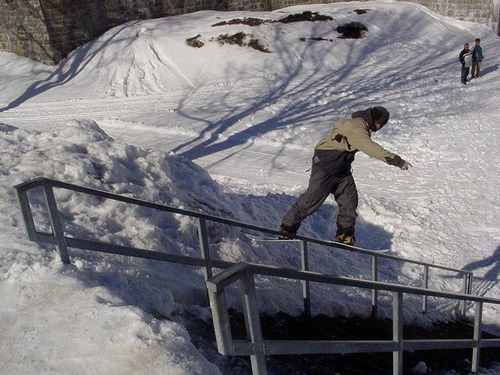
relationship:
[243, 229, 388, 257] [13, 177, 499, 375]
snowboard on railing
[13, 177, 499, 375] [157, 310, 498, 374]
railing around stairs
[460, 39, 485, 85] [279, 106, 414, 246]
people watching man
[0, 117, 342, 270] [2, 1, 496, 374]
pile of snow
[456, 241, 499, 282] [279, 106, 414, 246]
shadow of man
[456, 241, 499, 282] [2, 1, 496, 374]
shadow on snow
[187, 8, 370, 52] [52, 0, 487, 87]
dirt on hill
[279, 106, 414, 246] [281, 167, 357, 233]
man wearing pants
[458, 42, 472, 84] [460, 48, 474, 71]
people wearing a jacket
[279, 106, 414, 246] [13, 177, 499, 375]
man on railing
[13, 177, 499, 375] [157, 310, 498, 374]
railing going down stairs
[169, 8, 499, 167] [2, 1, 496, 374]
shadow on snow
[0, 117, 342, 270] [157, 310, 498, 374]
pile beside stairs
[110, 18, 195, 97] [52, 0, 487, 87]
tracks going down hill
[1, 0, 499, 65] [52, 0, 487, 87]
wall behind hill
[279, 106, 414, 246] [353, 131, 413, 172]
man has a arm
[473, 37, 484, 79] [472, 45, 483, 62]
person wearing a jacket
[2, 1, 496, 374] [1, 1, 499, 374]
snow on ground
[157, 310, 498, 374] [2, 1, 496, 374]
stairs going down snow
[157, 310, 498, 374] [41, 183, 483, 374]
stairs have poles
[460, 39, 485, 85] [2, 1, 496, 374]
people standing in snow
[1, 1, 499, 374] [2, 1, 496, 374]
ground covered in snow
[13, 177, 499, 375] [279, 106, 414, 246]
railing on side of man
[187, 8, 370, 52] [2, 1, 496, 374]
dirt on snow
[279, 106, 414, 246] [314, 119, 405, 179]
man wearing a jacket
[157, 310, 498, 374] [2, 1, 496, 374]
stairs have snow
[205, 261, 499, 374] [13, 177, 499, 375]
part of railing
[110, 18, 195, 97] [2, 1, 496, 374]
tracks in snow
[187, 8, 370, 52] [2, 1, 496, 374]
dirt in snow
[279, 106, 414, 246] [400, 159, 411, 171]
man has a hand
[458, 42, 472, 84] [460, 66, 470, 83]
people wearing pants